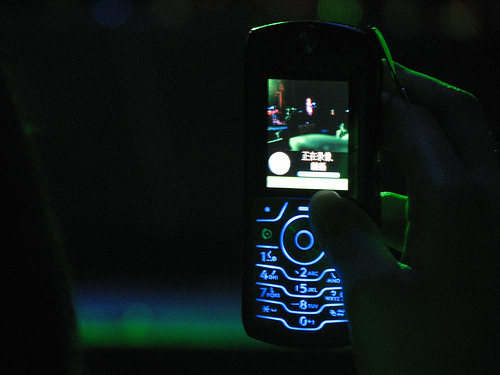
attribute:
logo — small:
[300, 147, 333, 162]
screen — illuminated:
[265, 75, 355, 201]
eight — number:
[285, 290, 318, 318]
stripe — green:
[73, 321, 245, 346]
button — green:
[259, 223, 274, 252]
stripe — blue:
[78, 303, 226, 320]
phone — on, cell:
[238, 16, 382, 349]